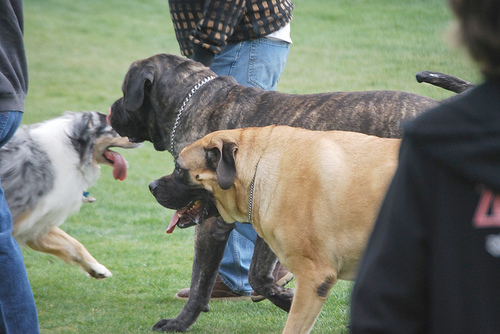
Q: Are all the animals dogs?
A: Yes, all the animals are dogs.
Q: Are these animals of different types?
A: No, all the animals are dogs.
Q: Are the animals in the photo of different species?
A: No, all the animals are dogs.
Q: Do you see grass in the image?
A: Yes, there is grass.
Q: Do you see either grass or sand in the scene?
A: Yes, there is grass.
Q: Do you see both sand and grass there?
A: No, there is grass but no sand.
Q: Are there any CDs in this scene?
A: No, there are no cds.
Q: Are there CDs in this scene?
A: No, there are no cds.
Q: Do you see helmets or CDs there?
A: No, there are no CDs or helmets.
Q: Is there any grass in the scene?
A: Yes, there is grass.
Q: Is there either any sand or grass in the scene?
A: Yes, there is grass.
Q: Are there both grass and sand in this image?
A: No, there is grass but no sand.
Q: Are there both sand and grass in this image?
A: No, there is grass but no sand.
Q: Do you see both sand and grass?
A: No, there is grass but no sand.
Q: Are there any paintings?
A: No, there are no paintings.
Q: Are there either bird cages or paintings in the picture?
A: No, there are no paintings or bird cages.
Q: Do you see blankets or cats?
A: No, there are no cats or blankets.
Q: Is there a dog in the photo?
A: Yes, there is a dog.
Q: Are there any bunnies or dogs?
A: Yes, there is a dog.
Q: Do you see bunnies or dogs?
A: Yes, there is a dog.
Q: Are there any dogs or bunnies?
A: Yes, there is a dog.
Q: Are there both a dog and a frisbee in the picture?
A: No, there is a dog but no frisbees.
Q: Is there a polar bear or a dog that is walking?
A: Yes, the dog is walking.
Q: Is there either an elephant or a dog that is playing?
A: Yes, the dog is playing.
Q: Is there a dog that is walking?
A: Yes, there is a dog that is walking.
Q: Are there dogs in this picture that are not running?
A: Yes, there is a dog that is walking.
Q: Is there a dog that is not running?
A: Yes, there is a dog that is walking.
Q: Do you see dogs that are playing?
A: Yes, there is a dog that is playing.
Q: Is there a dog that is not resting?
A: Yes, there is a dog that is playing.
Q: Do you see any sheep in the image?
A: No, there are no sheep.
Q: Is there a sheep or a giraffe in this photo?
A: No, there are no sheep or giraffes.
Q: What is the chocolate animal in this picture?
A: The animal is a dog.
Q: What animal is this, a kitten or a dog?
A: This is a dog.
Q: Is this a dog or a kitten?
A: This is a dog.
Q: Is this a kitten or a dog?
A: This is a dog.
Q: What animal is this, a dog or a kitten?
A: This is a dog.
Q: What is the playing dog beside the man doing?
A: The dog is walking.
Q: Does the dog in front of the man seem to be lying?
A: No, the dog is walking.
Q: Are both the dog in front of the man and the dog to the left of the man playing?
A: Yes, both the dog and the dog are playing.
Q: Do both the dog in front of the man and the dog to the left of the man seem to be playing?
A: Yes, both the dog and the dog are playing.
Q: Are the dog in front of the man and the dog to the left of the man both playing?
A: Yes, both the dog and the dog are playing.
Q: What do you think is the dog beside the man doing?
A: The dog is playing.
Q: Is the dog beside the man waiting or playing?
A: The dog is playing.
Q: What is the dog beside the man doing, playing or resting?
A: The dog is playing.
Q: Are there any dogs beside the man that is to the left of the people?
A: Yes, there is a dog beside the man.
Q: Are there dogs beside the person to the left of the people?
A: Yes, there is a dog beside the man.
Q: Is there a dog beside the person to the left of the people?
A: Yes, there is a dog beside the man.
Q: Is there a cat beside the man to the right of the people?
A: No, there is a dog beside the man.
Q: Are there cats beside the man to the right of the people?
A: No, there is a dog beside the man.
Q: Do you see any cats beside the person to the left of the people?
A: No, there is a dog beside the man.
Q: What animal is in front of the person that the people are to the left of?
A: The dog is in front of the man.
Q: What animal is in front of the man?
A: The dog is in front of the man.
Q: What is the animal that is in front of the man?
A: The animal is a dog.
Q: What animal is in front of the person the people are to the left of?
A: The animal is a dog.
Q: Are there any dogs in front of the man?
A: Yes, there is a dog in front of the man.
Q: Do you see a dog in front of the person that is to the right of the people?
A: Yes, there is a dog in front of the man.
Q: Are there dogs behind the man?
A: No, the dog is in front of the man.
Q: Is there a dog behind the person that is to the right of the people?
A: No, the dog is in front of the man.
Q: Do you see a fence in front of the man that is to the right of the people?
A: No, there is a dog in front of the man.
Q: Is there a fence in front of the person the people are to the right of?
A: No, there is a dog in front of the man.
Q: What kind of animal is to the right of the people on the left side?
A: The animal is a dog.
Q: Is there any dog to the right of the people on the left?
A: Yes, there is a dog to the right of the people.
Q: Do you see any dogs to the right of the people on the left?
A: Yes, there is a dog to the right of the people.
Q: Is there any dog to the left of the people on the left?
A: No, the dog is to the right of the people.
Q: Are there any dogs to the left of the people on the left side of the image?
A: No, the dog is to the right of the people.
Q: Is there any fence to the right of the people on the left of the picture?
A: No, there is a dog to the right of the people.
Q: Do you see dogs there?
A: Yes, there is a dog.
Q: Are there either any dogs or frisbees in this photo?
A: Yes, there is a dog.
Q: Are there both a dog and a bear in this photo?
A: No, there is a dog but no bears.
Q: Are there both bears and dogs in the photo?
A: No, there is a dog but no bears.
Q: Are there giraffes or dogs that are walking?
A: Yes, the dog is walking.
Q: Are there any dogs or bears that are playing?
A: Yes, the dog is playing.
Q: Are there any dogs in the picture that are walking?
A: Yes, there is a dog that is walking.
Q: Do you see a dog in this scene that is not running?
A: Yes, there is a dog that is walking .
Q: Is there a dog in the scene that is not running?
A: Yes, there is a dog that is walking.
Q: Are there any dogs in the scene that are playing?
A: Yes, there is a dog that is playing.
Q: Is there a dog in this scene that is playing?
A: Yes, there is a dog that is playing.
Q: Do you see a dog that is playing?
A: Yes, there is a dog that is playing.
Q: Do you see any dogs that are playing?
A: Yes, there is a dog that is playing.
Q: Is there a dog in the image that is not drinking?
A: Yes, there is a dog that is playing.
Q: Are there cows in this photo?
A: No, there are no cows.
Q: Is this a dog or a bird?
A: This is a dog.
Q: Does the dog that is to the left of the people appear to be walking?
A: Yes, the dog is walking.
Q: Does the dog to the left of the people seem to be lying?
A: No, the dog is walking.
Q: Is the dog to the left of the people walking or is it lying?
A: The dog is walking.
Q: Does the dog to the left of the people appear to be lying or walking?
A: The dog is walking.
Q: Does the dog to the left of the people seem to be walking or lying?
A: The dog is walking.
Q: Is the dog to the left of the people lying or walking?
A: The dog is walking.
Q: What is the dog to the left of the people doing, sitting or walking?
A: The dog is walking.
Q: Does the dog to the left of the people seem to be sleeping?
A: No, the dog is playing.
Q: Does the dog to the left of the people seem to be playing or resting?
A: The dog is playing.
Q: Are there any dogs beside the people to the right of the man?
A: Yes, there is a dog beside the people.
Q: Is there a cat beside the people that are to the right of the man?
A: No, there is a dog beside the people.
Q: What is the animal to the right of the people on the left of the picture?
A: The animal is a dog.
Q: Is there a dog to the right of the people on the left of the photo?
A: Yes, there is a dog to the right of the people.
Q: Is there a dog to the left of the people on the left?
A: No, the dog is to the right of the people.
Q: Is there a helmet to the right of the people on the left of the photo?
A: No, there is a dog to the right of the people.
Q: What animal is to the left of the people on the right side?
A: The animal is a dog.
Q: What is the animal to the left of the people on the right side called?
A: The animal is a dog.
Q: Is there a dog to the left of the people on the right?
A: Yes, there is a dog to the left of the people.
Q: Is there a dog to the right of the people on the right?
A: No, the dog is to the left of the people.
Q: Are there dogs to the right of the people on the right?
A: No, the dog is to the left of the people.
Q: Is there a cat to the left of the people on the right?
A: No, there is a dog to the left of the people.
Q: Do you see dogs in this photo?
A: Yes, there is a dog.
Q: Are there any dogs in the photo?
A: Yes, there is a dog.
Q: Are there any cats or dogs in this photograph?
A: Yes, there is a dog.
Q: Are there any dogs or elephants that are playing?
A: Yes, the dog is playing.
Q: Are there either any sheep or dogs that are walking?
A: Yes, the dog is walking.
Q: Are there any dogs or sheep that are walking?
A: Yes, the dog is walking.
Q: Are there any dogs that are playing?
A: Yes, there is a dog that is playing.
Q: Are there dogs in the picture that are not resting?
A: Yes, there is a dog that is playing.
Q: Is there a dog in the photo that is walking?
A: Yes, there is a dog that is walking.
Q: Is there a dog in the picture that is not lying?
A: Yes, there is a dog that is walking.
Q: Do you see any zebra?
A: No, there are no zebras.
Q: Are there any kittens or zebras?
A: No, there are no zebras or kittens.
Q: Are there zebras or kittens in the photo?
A: No, there are no zebras or kittens.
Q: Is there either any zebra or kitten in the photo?
A: No, there are no zebras or kittens.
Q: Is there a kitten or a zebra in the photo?
A: No, there are no zebras or kittens.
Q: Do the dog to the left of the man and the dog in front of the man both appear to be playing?
A: Yes, both the dog and the dog are playing.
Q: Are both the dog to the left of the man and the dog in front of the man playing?
A: Yes, both the dog and the dog are playing.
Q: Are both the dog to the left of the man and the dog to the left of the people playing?
A: Yes, both the dog and the dog are playing.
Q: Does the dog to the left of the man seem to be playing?
A: Yes, the dog is playing.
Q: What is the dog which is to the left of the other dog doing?
A: The dog is playing.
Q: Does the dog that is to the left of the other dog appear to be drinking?
A: No, the dog is playing.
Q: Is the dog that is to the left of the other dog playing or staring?
A: The dog is playing.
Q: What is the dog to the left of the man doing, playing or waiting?
A: The dog is playing.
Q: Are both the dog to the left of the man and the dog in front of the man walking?
A: Yes, both the dog and the dog are walking.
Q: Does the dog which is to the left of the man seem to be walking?
A: Yes, the dog is walking.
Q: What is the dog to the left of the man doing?
A: The dog is walking.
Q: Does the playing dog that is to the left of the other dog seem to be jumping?
A: No, the dog is walking.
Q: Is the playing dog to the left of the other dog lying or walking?
A: The dog is walking.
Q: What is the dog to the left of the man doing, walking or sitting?
A: The dog is walking.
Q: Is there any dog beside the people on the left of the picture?
A: Yes, there is a dog beside the people.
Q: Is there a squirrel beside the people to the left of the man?
A: No, there is a dog beside the people.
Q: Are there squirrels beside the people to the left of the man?
A: No, there is a dog beside the people.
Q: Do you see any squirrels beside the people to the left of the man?
A: No, there is a dog beside the people.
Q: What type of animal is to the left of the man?
A: The animal is a dog.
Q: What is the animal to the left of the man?
A: The animal is a dog.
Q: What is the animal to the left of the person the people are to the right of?
A: The animal is a dog.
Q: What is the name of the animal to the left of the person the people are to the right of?
A: The animal is a dog.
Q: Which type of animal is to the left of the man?
A: The animal is a dog.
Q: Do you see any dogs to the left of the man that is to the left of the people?
A: Yes, there is a dog to the left of the man.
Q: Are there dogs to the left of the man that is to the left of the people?
A: Yes, there is a dog to the left of the man.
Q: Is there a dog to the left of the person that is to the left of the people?
A: Yes, there is a dog to the left of the man.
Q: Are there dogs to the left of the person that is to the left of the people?
A: Yes, there is a dog to the left of the man.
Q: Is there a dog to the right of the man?
A: No, the dog is to the left of the man.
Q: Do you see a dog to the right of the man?
A: No, the dog is to the left of the man.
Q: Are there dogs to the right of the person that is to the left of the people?
A: No, the dog is to the left of the man.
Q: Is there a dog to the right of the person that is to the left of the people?
A: No, the dog is to the left of the man.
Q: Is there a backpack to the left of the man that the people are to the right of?
A: No, there is a dog to the left of the man.